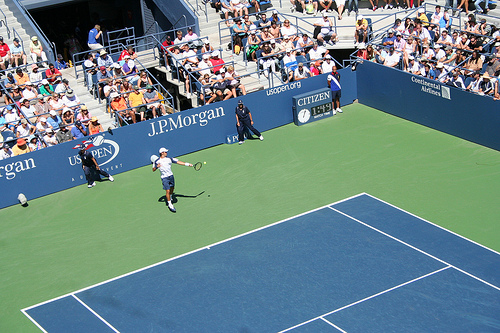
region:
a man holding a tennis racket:
[146, 124, 216, 214]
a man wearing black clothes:
[230, 86, 256, 151]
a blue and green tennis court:
[261, 155, 426, 332]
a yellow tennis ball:
[199, 135, 218, 172]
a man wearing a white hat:
[158, 142, 173, 162]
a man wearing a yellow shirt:
[129, 80, 142, 107]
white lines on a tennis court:
[282, 186, 418, 293]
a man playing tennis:
[127, 121, 207, 236]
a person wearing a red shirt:
[210, 42, 222, 75]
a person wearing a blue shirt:
[80, 21, 105, 58]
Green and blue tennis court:
[0, 211, 499, 331]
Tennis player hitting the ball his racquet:
[145, 140, 216, 217]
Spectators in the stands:
[0, 21, 341, 136]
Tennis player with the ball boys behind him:
[71, 97, 271, 197]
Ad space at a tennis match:
[146, 74, 454, 136]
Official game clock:
[289, 85, 336, 125]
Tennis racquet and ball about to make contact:
[189, 157, 214, 173]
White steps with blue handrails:
[0, 1, 48, 37]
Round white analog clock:
[296, 106, 311, 123]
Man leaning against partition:
[325, 62, 349, 117]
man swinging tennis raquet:
[147, 142, 202, 212]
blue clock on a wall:
[290, 85, 330, 125]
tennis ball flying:
[200, 156, 206, 166]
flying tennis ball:
[200, 155, 206, 165]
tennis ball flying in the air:
[201, 160, 206, 166]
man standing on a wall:
[325, 63, 341, 109]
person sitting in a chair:
[352, 11, 377, 48]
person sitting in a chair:
[315, 11, 338, 48]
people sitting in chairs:
[228, 8, 295, 52]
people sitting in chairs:
[190, 50, 234, 101]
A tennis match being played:
[0, 137, 487, 322]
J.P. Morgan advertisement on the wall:
[137, 97, 224, 142]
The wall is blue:
[107, 139, 215, 163]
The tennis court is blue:
[169, 221, 499, 318]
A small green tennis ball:
[201, 160, 208, 168]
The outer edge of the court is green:
[352, 114, 469, 219]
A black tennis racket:
[190, 157, 207, 173]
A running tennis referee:
[70, 137, 111, 189]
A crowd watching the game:
[51, 20, 283, 92]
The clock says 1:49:
[307, 100, 339, 127]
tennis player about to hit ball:
[149, 145, 208, 215]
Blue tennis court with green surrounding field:
[26, 193, 497, 330]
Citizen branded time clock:
[292, 91, 337, 126]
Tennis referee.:
[230, 97, 265, 145]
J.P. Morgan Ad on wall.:
[145, 109, 229, 136]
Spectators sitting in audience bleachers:
[3, 3, 231, 130]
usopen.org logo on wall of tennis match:
[263, 79, 309, 97]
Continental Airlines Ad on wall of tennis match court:
[406, 72, 463, 99]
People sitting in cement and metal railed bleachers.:
[355, 3, 497, 57]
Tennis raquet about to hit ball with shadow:
[188, 153, 216, 202]